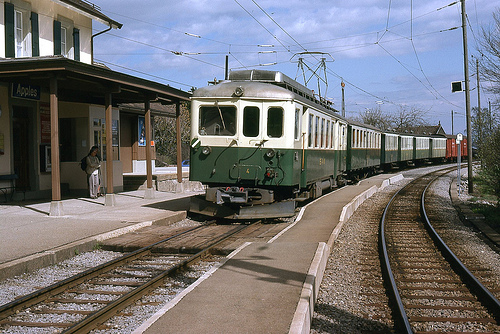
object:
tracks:
[0, 218, 253, 333]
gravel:
[0, 248, 230, 333]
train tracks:
[376, 163, 500, 333]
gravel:
[310, 161, 499, 333]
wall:
[0, 85, 154, 198]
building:
[0, 0, 194, 217]